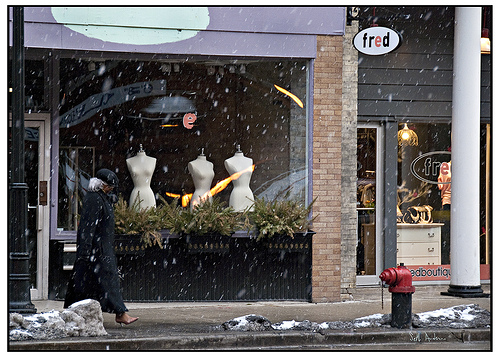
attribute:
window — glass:
[57, 60, 308, 232]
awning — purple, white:
[7, 5, 349, 59]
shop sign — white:
[351, 25, 403, 56]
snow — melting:
[118, 284, 334, 311]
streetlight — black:
[394, 118, 419, 150]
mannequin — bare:
[189, 147, 216, 209]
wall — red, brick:
[304, 26, 344, 303]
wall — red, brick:
[313, 28, 350, 302]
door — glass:
[359, 123, 381, 281]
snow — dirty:
[424, 289, 493, 348]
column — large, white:
[445, 16, 492, 142]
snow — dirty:
[412, 289, 468, 328]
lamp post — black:
[8, 4, 38, 314]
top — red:
[379, 260, 415, 291]